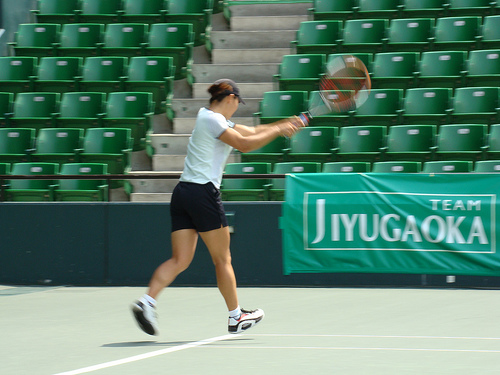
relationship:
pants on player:
[169, 182, 229, 232] [128, 77, 304, 337]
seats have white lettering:
[446, 14, 499, 89] [432, 50, 498, 62]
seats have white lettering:
[395, 124, 493, 170] [403, 125, 475, 140]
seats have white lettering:
[122, 19, 183, 109] [99, 59, 164, 64]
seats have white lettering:
[26, 27, 77, 114] [50, 132, 122, 142]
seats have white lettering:
[17, 130, 137, 188] [27, 161, 99, 176]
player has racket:
[128, 79, 304, 336] [275, 47, 385, 146]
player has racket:
[128, 79, 304, 336] [301, 56, 369, 124]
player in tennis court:
[128, 79, 304, 336] [4, 286, 498, 373]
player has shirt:
[128, 79, 304, 336] [178, 101, 235, 188]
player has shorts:
[128, 79, 304, 336] [164, 177, 233, 234]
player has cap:
[128, 79, 304, 336] [208, 78, 248, 102]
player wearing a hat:
[128, 79, 304, 336] [192, 69, 277, 124]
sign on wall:
[280, 164, 498, 286] [1, 199, 499, 287]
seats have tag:
[325, 43, 456, 141] [99, 60, 127, 68]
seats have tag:
[325, 43, 456, 141] [436, 51, 452, 64]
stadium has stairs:
[3, 3, 498, 285] [122, 3, 309, 207]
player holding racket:
[128, 79, 304, 336] [282, 54, 381, 134]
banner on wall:
[278, 170, 499, 279] [7, 194, 199, 283]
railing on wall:
[7, 170, 287, 178] [3, 172, 495, 287]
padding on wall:
[50, 204, 145, 285] [5, 205, 117, 285]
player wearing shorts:
[128, 79, 304, 336] [164, 178, 238, 237]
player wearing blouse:
[128, 79, 304, 336] [179, 107, 235, 189]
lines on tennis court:
[61, 331, 240, 373] [4, 286, 498, 373]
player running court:
[128, 79, 304, 336] [304, 285, 488, 373]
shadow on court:
[98, 335, 255, 350] [0, 201, 500, 374]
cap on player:
[208, 78, 246, 104] [128, 79, 304, 336]